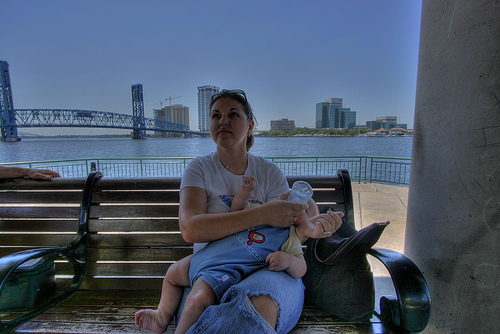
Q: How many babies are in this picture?
A: One.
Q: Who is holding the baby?
A: Mother.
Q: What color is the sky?
A: Blue.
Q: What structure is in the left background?
A: Bridge.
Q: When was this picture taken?
A: Daytime.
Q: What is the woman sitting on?
A: Bench.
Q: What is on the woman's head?
A: Sunglasses.